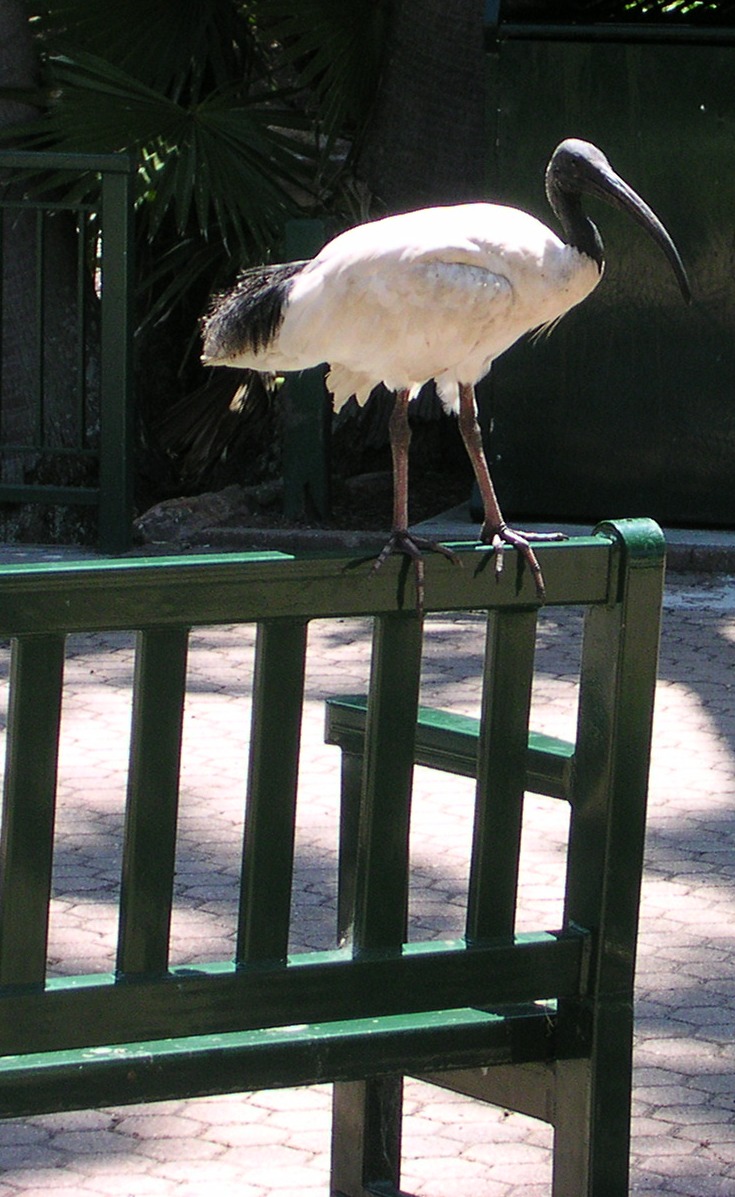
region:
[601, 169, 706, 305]
the beck of a bird is long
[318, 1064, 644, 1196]
a leg of a bench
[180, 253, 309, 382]
the tail is color black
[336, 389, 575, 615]
the long legs of a bird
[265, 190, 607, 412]
the body is color white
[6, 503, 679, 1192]
the bench is color green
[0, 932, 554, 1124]
the sit of the bench is green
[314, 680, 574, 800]
the armrest of bench is green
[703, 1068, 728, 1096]
The black man is eating.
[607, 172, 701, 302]
black beak of the bird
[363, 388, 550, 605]
long legs of the bird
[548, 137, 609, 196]
black head of the bird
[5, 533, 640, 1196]
green bench the bird is standing on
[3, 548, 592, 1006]
back of the bench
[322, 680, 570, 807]
armrest on the green bench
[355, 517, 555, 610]
talons of the bird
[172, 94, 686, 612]
bird perched on a bench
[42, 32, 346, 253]
leaf of a palm tree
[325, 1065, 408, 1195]
leg of a bench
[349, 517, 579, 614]
feet of a bird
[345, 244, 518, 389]
right wing of a bird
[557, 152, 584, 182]
eye of a bird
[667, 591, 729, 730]
shadow casted on the ground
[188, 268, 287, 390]
tail of a bird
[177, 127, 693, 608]
black and white bird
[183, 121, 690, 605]
black and white bird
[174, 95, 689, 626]
black and white bird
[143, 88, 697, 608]
black and white bird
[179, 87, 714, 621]
black and white bird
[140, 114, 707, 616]
black and white bird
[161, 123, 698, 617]
black and white bird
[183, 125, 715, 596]
black and white bird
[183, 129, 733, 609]
black and white bird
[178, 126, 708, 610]
black and white bird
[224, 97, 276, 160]
green leaves on the tree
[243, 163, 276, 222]
green leaves on the tree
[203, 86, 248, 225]
green leaves on the tree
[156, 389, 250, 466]
green leaves on the tree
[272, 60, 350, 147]
green leaves on the tree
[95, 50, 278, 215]
green leaves on the tree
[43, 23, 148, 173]
green leaves on the tree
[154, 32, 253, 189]
green leaves on the tree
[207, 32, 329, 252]
green leaves on the tree